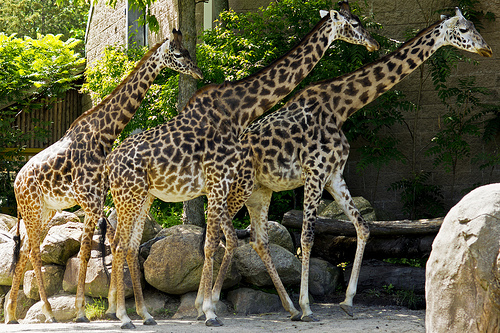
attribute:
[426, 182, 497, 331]
boulder — round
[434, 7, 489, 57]
head — brown, white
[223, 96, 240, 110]
spot — brown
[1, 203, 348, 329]
rocks — large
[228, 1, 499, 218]
wall — brown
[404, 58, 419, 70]
spot — brown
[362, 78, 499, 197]
wall — brick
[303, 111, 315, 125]
spot — brown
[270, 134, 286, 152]
spot — brown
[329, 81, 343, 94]
spot — brown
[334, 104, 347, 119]
spot — brown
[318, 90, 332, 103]
spot — brown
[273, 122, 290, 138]
spot — brown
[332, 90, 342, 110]
spot — brown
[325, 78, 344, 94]
spot — brown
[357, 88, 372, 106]
spot — brown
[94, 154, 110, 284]
tail — long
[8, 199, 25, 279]
tail — long